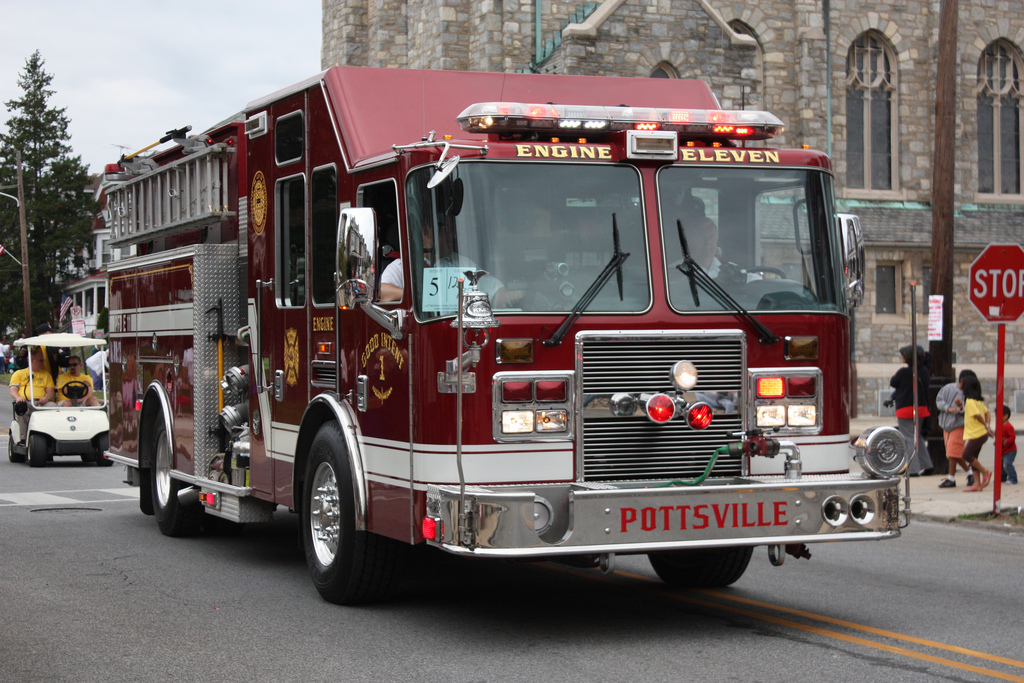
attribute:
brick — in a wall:
[904, 130, 928, 180]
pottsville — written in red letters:
[617, 497, 801, 532]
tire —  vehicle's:
[298, 423, 433, 607]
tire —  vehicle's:
[300, 423, 417, 611]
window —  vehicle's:
[402, 169, 645, 317]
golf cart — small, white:
[6, 318, 123, 476]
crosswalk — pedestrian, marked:
[2, 474, 160, 514]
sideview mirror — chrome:
[328, 197, 404, 334]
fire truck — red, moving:
[92, 65, 918, 610]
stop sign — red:
[963, 242, 992, 323]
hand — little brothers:
[984, 420, 993, 436]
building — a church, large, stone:
[321, 5, 993, 399]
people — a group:
[874, 335, 989, 487]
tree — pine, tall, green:
[0, 46, 106, 343]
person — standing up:
[882, 335, 937, 470]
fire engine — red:
[70, 44, 920, 624]